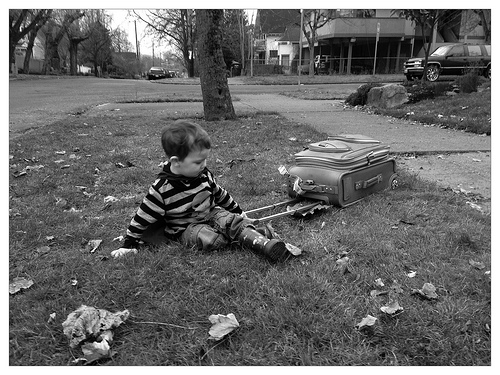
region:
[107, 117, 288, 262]
Toddler sitting in the grass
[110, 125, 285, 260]
Toddler with striped shirt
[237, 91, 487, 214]
sidewalk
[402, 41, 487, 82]
black SUV stopped at the stop sign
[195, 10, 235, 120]
tree right behind the boy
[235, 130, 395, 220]
a suitcase laying in the grass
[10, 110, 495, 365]
a grassy patch beside the sidewalk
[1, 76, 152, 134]
street on the left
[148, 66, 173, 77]
cars parked along the street in the distance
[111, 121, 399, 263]
boy sitting in grass with his suitcase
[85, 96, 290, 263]
little boy sitting on ground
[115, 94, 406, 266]
little boy touching suit case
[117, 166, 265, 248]
boy's shirt is striped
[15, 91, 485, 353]
leaves on the grass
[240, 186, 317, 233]
suitcase handle pulled up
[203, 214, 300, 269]
boy is wearing rain boots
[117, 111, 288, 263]
boy is looking down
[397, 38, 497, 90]
car parked on side of road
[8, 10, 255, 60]
trees have no leaves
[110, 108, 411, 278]
young boy sitting in grass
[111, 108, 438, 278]
young boy sitting next to luggage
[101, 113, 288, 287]
young boy in striped shirt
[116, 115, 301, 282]
young boy sitting on the ground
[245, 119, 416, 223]
luggage with wheels on the ground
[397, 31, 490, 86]
black suv on the street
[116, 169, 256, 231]
striped short of young boy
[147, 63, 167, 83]
car parked on the street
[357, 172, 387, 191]
handle on luggage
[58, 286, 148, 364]
large leaves on the ground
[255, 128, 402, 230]
a suit case in the grass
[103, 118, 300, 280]
a little boy in the grass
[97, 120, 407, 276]
a little boy pulling a suite case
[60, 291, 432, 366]
died leaves on the ground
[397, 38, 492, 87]
a car parked on the curb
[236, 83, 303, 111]
a concrete side walk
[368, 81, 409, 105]
a brown rock in a yard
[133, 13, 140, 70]
a wood electric pole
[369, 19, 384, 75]
a sign across the street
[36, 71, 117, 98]
a black top road